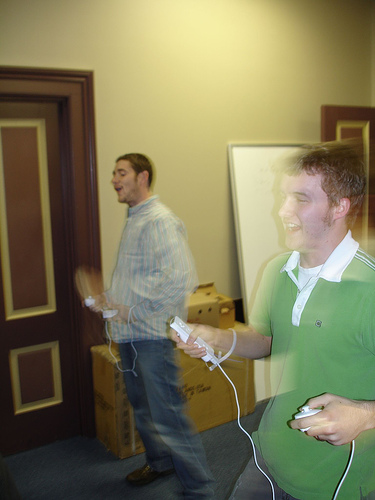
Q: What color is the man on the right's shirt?
A: Green.